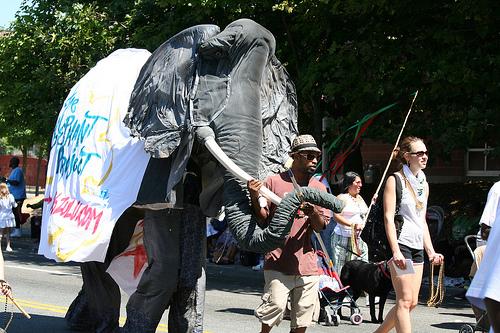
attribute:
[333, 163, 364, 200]
hair — black 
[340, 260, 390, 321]
dog — brown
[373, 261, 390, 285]
collar — red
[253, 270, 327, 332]
shorts — beige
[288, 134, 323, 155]
hat — gray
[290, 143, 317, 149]
stripe — black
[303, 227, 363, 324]
stroller — for baby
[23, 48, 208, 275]
banner — white, yellow, red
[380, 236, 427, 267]
shorts — black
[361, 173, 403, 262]
bag — black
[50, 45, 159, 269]
sign — white, large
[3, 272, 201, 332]
street marking — yellow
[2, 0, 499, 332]
afternoon parade — large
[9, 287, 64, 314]
line — yellow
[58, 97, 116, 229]
letters — blue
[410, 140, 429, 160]
shades — reddish, brown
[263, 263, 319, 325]
shorts — brown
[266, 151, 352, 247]
shirt — short sleeved